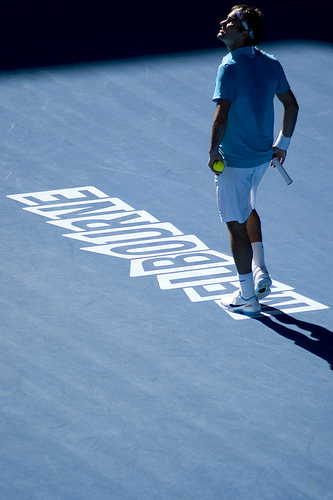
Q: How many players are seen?
A: One.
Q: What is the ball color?
A: Yellow.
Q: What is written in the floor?
A: Welbourne.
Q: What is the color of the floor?
A: Blue.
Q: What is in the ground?
A: Shadow.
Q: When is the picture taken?
A: Daytime.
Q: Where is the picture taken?
A: On a tennis court.